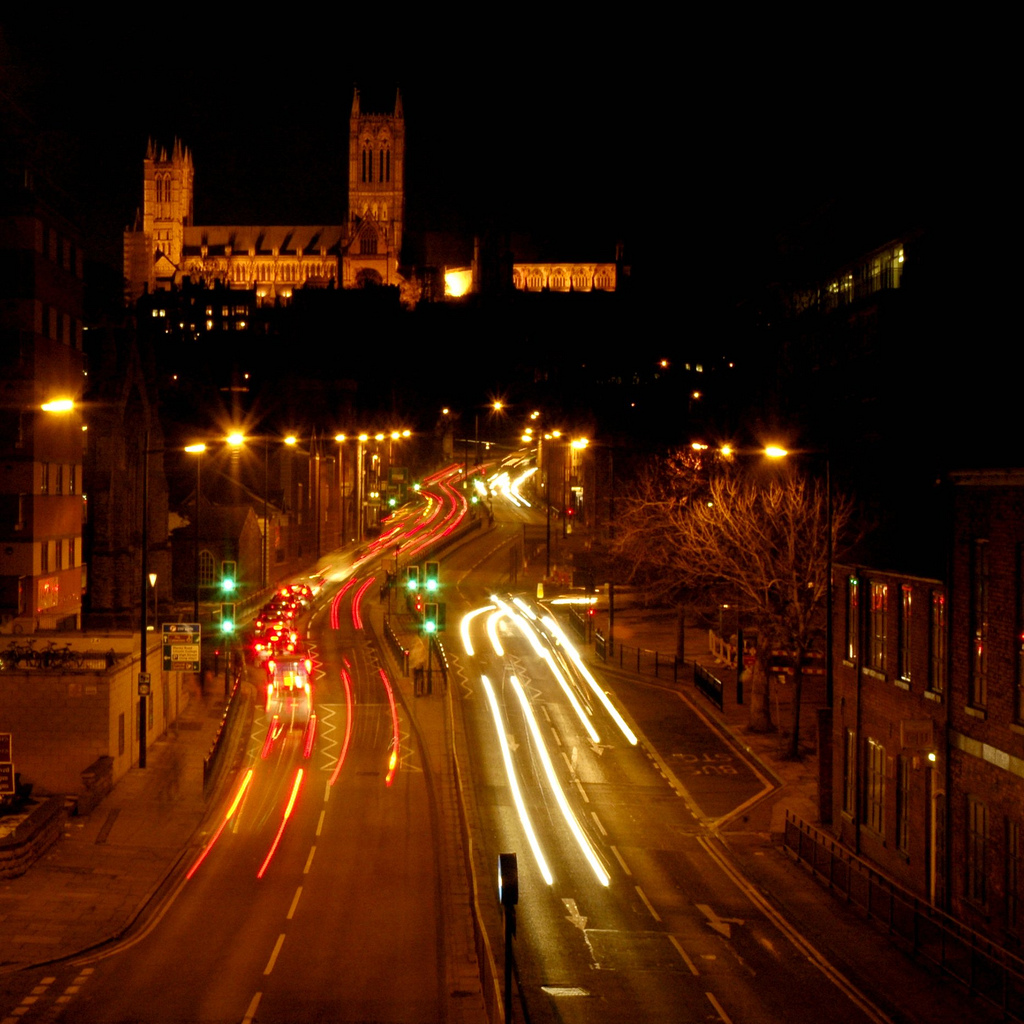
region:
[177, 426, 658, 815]
many cars on street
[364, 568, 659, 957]
lights on the street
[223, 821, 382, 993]
lines on the sidewalk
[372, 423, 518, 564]
cars in the distance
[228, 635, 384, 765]
red lights on street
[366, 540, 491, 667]
green lights on street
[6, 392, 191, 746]
buildings next to street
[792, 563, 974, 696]
windows on the building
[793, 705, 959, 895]
bottom windows on building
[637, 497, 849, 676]
tree next to street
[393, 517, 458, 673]
THE TRAFFIC LIGHTS ARE ON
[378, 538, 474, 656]
the traffic lights are green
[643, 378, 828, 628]
the street lights are on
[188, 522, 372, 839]
the brake lights are red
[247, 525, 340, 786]
the brake lights are on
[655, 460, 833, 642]
the tree is bare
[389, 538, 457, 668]
the traffic lights are in the middle of the street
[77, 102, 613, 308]
the building is lit up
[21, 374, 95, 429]
yellow colored light from the street light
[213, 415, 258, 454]
yellow colored light from the street light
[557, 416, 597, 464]
yellow colored light from the street light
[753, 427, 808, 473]
yellow colored light from the street light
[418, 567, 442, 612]
green colored light of the stoplight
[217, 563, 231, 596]
green colored light of the stoplight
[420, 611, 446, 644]
green colored light of the stoplight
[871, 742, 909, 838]
a window on the building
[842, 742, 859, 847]
a window on the building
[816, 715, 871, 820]
a window on the building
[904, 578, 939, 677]
a window on the building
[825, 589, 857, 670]
a window on the building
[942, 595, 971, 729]
a window on the building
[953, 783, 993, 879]
a window on the building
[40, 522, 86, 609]
a window on the building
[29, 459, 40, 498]
a window on a building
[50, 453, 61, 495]
a window on a building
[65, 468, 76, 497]
a window on a building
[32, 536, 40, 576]
a window on a building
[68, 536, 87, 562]
a window on a building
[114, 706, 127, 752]
a window on a building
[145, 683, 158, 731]
a window on a building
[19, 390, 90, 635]
a building in a city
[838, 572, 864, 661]
Window of a building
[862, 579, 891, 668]
Window of a building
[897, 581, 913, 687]
Window of a building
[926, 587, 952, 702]
Window of a building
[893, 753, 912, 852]
Window of a building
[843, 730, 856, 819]
Window of a building